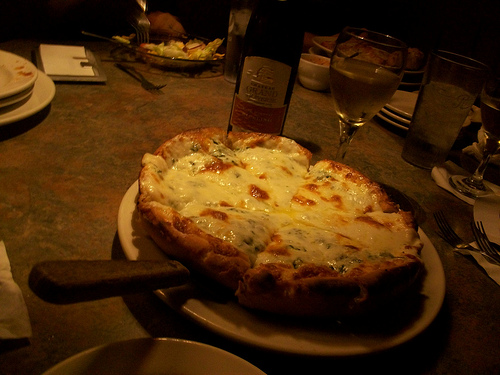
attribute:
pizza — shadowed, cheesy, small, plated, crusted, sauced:
[141, 132, 425, 317]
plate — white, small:
[120, 143, 446, 356]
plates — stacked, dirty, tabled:
[1, 49, 59, 129]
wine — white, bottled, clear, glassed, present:
[333, 30, 401, 120]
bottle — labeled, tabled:
[226, 2, 304, 143]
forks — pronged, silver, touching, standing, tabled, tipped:
[430, 212, 498, 268]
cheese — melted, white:
[157, 146, 405, 265]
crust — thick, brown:
[138, 129, 419, 321]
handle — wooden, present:
[29, 258, 187, 302]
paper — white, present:
[40, 41, 102, 82]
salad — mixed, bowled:
[127, 32, 220, 64]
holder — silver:
[27, 39, 109, 89]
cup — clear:
[402, 42, 484, 169]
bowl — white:
[43, 323, 269, 374]